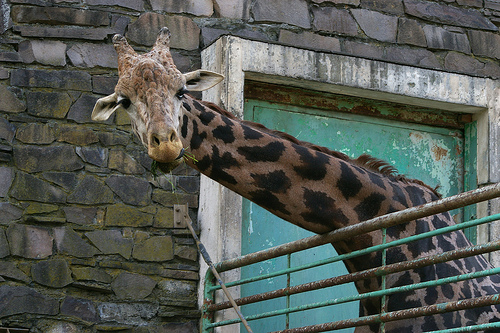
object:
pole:
[180, 206, 256, 333]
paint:
[258, 221, 262, 225]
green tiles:
[104, 204, 155, 227]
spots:
[291, 155, 332, 181]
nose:
[145, 127, 183, 162]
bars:
[274, 292, 499, 332]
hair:
[290, 130, 398, 181]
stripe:
[291, 142, 306, 166]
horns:
[111, 32, 138, 57]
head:
[87, 25, 230, 167]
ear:
[169, 55, 239, 93]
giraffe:
[88, 25, 500, 333]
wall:
[0, 0, 498, 333]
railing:
[200, 178, 498, 332]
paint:
[236, 93, 479, 328]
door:
[239, 70, 500, 333]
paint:
[378, 269, 498, 285]